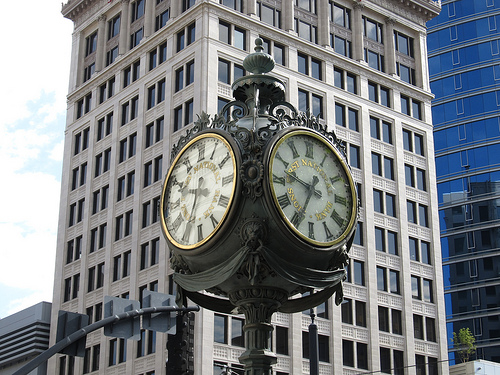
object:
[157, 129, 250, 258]
clocks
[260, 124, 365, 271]
clock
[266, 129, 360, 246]
face